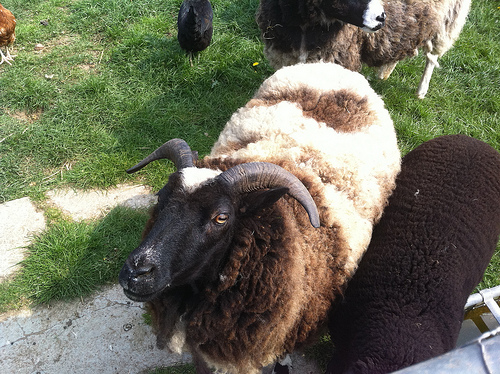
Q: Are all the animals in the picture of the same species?
A: Yes, all the animals are sheep.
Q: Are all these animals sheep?
A: Yes, all the animals are sheep.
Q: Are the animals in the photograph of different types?
A: No, all the animals are sheep.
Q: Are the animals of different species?
A: No, all the animals are sheep.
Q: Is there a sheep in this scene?
A: Yes, there is a sheep.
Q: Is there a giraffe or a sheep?
A: Yes, there is a sheep.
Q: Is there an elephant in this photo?
A: No, there are no elephants.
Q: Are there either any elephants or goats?
A: No, there are no elephants or goats.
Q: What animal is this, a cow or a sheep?
A: This is a sheep.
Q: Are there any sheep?
A: Yes, there is a sheep.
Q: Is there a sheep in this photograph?
A: Yes, there is a sheep.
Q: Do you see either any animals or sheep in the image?
A: Yes, there is a sheep.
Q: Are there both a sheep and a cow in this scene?
A: No, there is a sheep but no cows.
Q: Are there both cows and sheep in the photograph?
A: No, there is a sheep but no cows.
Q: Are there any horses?
A: No, there are no horses.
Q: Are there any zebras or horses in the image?
A: No, there are no horses or zebras.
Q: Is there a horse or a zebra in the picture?
A: No, there are no horses or zebras.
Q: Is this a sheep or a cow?
A: This is a sheep.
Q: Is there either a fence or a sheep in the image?
A: Yes, there is a sheep.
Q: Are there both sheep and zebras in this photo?
A: No, there is a sheep but no zebras.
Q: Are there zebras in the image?
A: No, there are no zebras.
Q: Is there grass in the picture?
A: Yes, there is grass.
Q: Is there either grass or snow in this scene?
A: Yes, there is grass.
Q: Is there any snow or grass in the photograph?
A: Yes, there is grass.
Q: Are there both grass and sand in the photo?
A: No, there is grass but no sand.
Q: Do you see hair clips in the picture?
A: No, there are no hair clips.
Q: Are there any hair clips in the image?
A: No, there are no hair clips.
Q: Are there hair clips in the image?
A: No, there are no hair clips.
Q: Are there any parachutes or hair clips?
A: No, there are no hair clips or parachutes.